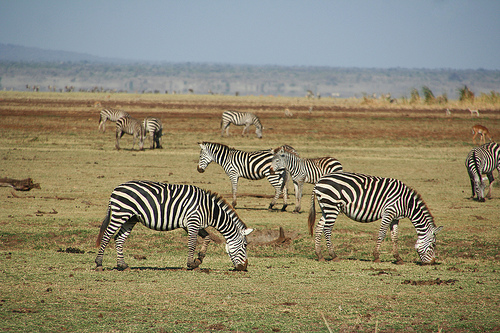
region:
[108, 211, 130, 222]
black stripe on zebra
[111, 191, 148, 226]
black stripe on zebra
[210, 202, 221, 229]
black stripe on zebra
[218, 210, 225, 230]
black stripe on zebra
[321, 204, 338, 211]
black stripe on zebra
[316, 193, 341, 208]
black stripe on zebra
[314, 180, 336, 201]
black stripe on zebra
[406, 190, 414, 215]
black stripe on zebra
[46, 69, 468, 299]
several zebra in a field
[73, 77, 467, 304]
several zebra eating grass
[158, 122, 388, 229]
two zebra standing but not eating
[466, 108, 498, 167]
one deer with the zebra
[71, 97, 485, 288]
several black and white zebras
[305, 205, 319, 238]
brown hairs on tail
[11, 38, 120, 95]
a mountain in the distance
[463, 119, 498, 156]
one brown deer eating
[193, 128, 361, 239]
two zebra not eating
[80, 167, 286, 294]
white zebra with black stripes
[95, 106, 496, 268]
the animals in the large field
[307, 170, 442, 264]
the zebra with its head down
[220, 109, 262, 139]
the zebra with its head down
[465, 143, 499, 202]
the zebra with its head down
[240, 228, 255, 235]
the ear on the zebra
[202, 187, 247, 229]
the mane on the zebra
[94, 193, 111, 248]
the tail on the zebra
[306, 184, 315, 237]
the tail on the zebra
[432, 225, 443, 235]
the ear on the zebra's head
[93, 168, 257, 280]
black and white striped zebra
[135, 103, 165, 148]
black and white striped zebra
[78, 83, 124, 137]
black and white striped zebra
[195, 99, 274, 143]
black and white striped zebra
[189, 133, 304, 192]
black and white striped zebra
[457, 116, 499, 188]
black and white striped zebra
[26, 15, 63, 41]
white clouds in blue sky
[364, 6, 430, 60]
white clouds in blue sky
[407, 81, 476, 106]
small group of arid trees with barely any green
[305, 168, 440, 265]
zebra pointed to the right and grazing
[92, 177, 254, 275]
grazing zebra facing to the right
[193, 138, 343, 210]
two zebras standing and facing the same direction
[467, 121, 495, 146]
small light brown gazelle in the background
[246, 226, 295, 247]
pile of dry arid mud mixed with zebra excrement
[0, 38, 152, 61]
small mountain in the background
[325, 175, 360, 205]
crazy black and white stripe design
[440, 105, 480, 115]
two extremely light colored deer-like animals in the background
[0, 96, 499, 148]
dry arid brown what was grassy field covered in dirty dried mud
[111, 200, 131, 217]
black stripe on zebra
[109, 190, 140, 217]
black stripe on zebra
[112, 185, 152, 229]
black stripe on zebra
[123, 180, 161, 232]
black stripe on zebra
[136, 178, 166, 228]
black stripe on zebra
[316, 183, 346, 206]
black stripe on zebra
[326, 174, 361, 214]
black stripe on zebra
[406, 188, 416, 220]
black stripe on zebra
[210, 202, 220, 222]
black stripe on zebra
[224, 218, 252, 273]
Head of a zebra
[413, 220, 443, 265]
Head of a zebra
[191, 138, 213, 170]
Head of a zebra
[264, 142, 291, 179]
Head of a zebra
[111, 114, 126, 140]
Head of a zebra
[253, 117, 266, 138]
Head of a zebra